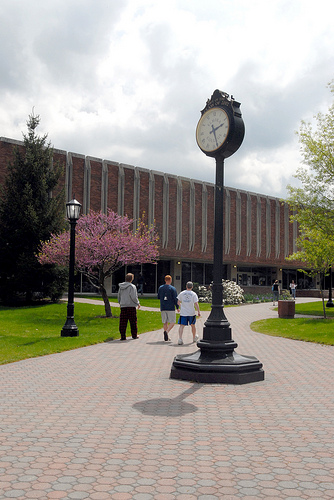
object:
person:
[289, 276, 297, 301]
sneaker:
[177, 337, 183, 345]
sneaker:
[191, 335, 198, 344]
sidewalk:
[0, 297, 333, 499]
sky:
[0, 0, 333, 208]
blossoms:
[32, 205, 161, 276]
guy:
[116, 272, 142, 341]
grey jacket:
[116, 280, 141, 309]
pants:
[117, 305, 138, 340]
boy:
[176, 280, 202, 348]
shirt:
[174, 289, 198, 319]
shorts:
[178, 314, 198, 327]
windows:
[192, 262, 205, 290]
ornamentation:
[199, 89, 244, 118]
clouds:
[0, 0, 333, 209]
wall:
[0, 137, 332, 265]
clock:
[194, 105, 230, 155]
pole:
[196, 160, 241, 353]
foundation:
[168, 347, 264, 387]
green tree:
[282, 184, 333, 319]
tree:
[32, 205, 162, 317]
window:
[141, 265, 157, 296]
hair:
[164, 274, 171, 284]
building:
[0, 133, 333, 298]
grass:
[248, 315, 334, 348]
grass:
[82, 295, 236, 313]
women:
[270, 278, 281, 306]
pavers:
[0, 298, 333, 500]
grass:
[0, 299, 182, 365]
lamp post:
[59, 222, 79, 337]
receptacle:
[276, 299, 294, 319]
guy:
[156, 272, 181, 342]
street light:
[59, 196, 84, 336]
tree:
[0, 103, 69, 310]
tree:
[281, 76, 333, 267]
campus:
[1, 294, 333, 499]